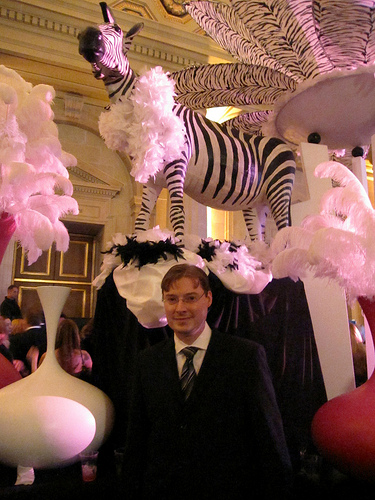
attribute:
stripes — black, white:
[184, 107, 297, 203]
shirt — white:
[172, 333, 207, 376]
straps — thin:
[70, 336, 94, 363]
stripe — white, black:
[192, 121, 284, 176]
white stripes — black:
[193, 119, 234, 193]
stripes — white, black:
[186, 109, 267, 194]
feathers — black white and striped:
[166, 0, 374, 136]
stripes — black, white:
[251, 148, 272, 179]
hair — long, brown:
[144, 260, 221, 301]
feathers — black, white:
[104, 229, 252, 270]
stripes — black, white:
[113, 104, 266, 217]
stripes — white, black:
[264, 160, 300, 207]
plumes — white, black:
[133, 4, 372, 155]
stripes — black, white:
[178, 133, 279, 191]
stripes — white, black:
[203, 127, 275, 196]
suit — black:
[130, 325, 295, 498]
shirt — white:
[168, 325, 231, 382]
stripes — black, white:
[203, 120, 253, 204]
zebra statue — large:
[100, 51, 305, 236]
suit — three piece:
[148, 356, 159, 386]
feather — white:
[27, 211, 40, 214]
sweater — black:
[0, 297, 26, 335]